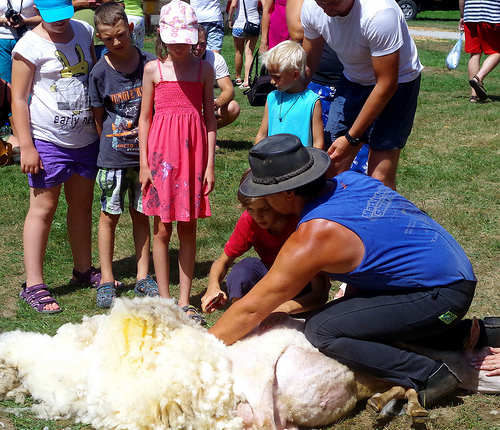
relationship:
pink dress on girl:
[156, 82, 201, 220] [19, 11, 104, 260]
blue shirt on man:
[361, 195, 386, 202] [244, 141, 466, 396]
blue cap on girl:
[28, 3, 93, 25] [19, 11, 104, 260]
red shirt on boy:
[238, 219, 284, 260] [217, 172, 313, 307]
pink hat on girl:
[166, 5, 204, 41] [19, 11, 104, 260]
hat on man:
[247, 147, 316, 182] [244, 141, 466, 396]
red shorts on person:
[462, 22, 496, 57] [442, 8, 498, 82]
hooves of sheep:
[362, 375, 437, 425] [269, 320, 388, 429]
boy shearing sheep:
[217, 172, 313, 307] [269, 320, 388, 429]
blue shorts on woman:
[236, 27, 266, 47] [233, 4, 266, 87]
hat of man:
[247, 147, 316, 182] [244, 141, 466, 396]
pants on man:
[312, 278, 470, 403] [244, 141, 466, 396]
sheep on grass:
[269, 320, 388, 429] [443, 94, 474, 141]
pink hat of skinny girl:
[166, 5, 204, 41] [147, 16, 206, 288]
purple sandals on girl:
[12, 274, 97, 305] [19, 11, 104, 260]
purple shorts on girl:
[20, 135, 114, 186] [19, 11, 104, 260]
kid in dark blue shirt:
[84, 5, 154, 255] [98, 66, 144, 166]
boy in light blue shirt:
[217, 172, 313, 307] [269, 92, 320, 142]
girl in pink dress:
[19, 11, 104, 260] [156, 82, 201, 220]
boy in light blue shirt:
[262, 40, 325, 161] [269, 92, 320, 142]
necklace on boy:
[273, 95, 308, 120] [262, 40, 325, 161]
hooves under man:
[362, 375, 437, 425] [244, 141, 466, 396]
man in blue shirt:
[244, 141, 466, 396] [345, 174, 451, 275]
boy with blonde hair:
[262, 40, 325, 161] [264, 49, 319, 78]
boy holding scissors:
[217, 172, 313, 307] [208, 288, 221, 317]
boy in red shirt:
[217, 172, 313, 307] [238, 219, 284, 260]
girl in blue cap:
[19, 11, 104, 260] [28, 3, 93, 25]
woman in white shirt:
[233, 4, 266, 87] [240, 4, 263, 31]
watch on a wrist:
[348, 129, 362, 148] [343, 123, 364, 153]